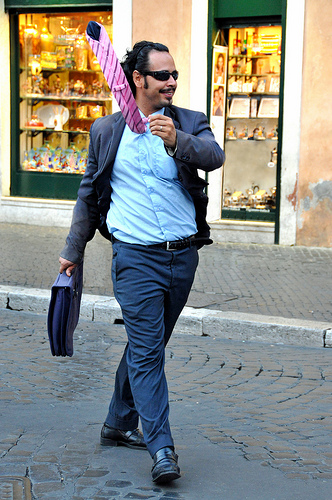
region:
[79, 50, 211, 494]
the man is walking at the street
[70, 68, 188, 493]
the man is walking at the street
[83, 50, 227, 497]
the man is walking at the street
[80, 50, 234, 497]
the man is walking at the street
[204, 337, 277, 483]
the pavement is wet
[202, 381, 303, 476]
the pavement is wet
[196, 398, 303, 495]
the pavement is wet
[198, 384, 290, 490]
the pavement is wet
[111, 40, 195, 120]
face of the person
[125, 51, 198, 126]
a person face smiling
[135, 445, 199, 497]
shoe of the person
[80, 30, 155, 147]
a beautiful view of tie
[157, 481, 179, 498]
shadow on the ground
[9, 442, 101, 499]
clean and neat ground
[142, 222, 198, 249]
belt of the person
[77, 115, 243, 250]
a man wearing suit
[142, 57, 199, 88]
spects of the person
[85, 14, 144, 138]
tie is blowing up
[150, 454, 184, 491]
front of the foot lifted off the ground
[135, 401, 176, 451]
wrinkles on the bottom of the pants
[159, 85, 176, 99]
smile on the face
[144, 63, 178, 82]
sunglasses on the face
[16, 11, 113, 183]
various objects on display in the window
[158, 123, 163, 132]
silver ring around the finger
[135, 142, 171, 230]
buttons down the shirt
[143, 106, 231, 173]
arm is bent at the elbow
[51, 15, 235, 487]
man walking down the street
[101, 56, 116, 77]
the tie has stripes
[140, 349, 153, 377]
the pants are blue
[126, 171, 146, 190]
the shirt is light blue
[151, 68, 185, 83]
he is wearing sunglasses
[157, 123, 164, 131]
he is wearing a ring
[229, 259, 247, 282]
the sidewalk is made of bricks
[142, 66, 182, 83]
pair of black sunglasses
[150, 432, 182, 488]
black leather shoe on a foot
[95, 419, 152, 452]
black leather shoe on a foot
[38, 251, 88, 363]
blue briefcase being held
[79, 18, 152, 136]
purple tie flowing in the wind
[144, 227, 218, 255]
black belt with silver buckle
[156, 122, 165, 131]
silver ring on a finger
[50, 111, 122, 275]
arm of a person walking on the street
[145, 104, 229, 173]
arm of a person walking on the street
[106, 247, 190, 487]
leg of a person walking on the street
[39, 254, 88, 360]
purple suitcase in right hand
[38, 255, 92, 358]
purple suitcase in right hand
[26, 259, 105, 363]
purple suitcase in right hand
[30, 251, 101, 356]
purple suitcase in right hand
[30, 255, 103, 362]
purple suitcase in right hand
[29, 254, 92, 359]
purple suitcase in right hand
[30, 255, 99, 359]
purple suitcase in right hand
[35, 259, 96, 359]
purple suitcase in right hand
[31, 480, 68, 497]
dark colored wet brick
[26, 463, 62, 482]
dark colored wet brick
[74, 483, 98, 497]
dark colored wet brick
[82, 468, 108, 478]
dark colored wet brick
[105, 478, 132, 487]
dark colored wet brick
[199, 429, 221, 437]
dark colored wet brick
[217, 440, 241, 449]
dark colored wet brick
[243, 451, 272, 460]
dark colored wet brick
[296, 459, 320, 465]
dark colored wet brick